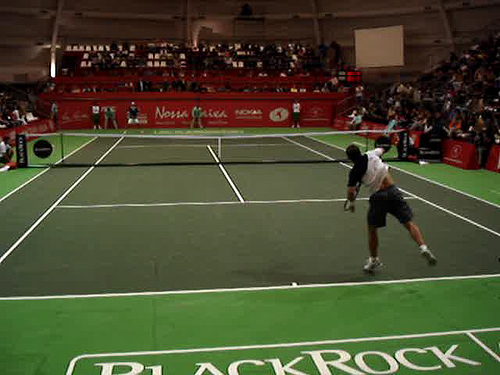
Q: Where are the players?
A: In the court.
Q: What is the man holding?
A: A racket.